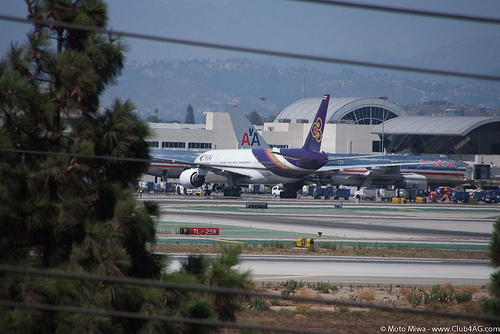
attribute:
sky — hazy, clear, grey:
[132, 11, 476, 79]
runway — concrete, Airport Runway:
[206, 199, 466, 229]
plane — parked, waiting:
[185, 136, 326, 184]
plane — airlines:
[244, 123, 468, 180]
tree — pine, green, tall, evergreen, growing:
[10, 3, 139, 288]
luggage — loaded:
[309, 184, 369, 198]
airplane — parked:
[325, 145, 481, 187]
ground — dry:
[186, 233, 483, 265]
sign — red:
[183, 208, 225, 242]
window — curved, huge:
[302, 86, 399, 129]